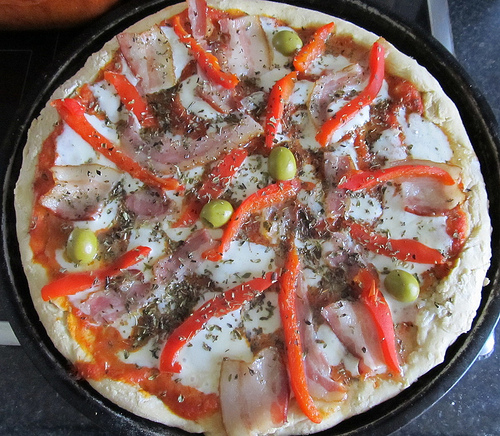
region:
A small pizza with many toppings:
[8, 3, 494, 433]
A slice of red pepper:
[277, 246, 321, 423]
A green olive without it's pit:
[198, 200, 234, 228]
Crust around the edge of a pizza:
[38, 304, 184, 425]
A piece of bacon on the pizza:
[39, 160, 125, 220]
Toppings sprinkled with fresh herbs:
[53, 85, 235, 229]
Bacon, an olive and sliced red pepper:
[339, 217, 449, 382]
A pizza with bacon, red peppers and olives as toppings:
[4, 3, 490, 433]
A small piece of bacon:
[113, 27, 180, 96]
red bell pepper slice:
[278, 245, 332, 427]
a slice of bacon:
[212, 336, 305, 434]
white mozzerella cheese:
[51, 104, 132, 179]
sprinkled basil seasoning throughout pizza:
[110, 60, 407, 335]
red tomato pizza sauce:
[21, 221, 61, 267]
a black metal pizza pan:
[5, 0, 495, 431]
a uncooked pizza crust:
[5, 10, 495, 435]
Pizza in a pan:
[40, 46, 412, 418]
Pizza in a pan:
[30, 20, 412, 408]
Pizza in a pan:
[13, 182, 434, 425]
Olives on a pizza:
[66, 228, 118, 265]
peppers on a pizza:
[156, 280, 288, 363]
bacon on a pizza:
[203, 320, 305, 433]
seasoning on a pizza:
[63, 120, 357, 351]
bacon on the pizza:
[121, 28, 183, 93]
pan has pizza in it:
[3, 1, 499, 434]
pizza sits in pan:
[14, 0, 493, 434]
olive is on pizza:
[267, 146, 297, 182]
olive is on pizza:
[199, 199, 234, 228]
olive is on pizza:
[382, 268, 424, 303]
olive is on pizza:
[64, 224, 97, 269]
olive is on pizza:
[271, 29, 301, 57]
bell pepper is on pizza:
[349, 266, 404, 379]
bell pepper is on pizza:
[336, 161, 463, 198]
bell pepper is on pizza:
[36, 243, 154, 300]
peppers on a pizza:
[51, 97, 171, 214]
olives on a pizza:
[65, 224, 117, 286]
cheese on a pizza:
[185, 328, 233, 376]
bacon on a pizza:
[201, 360, 272, 427]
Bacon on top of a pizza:
[100, 28, 383, 273]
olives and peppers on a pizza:
[196, 148, 346, 283]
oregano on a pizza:
[136, 124, 376, 349]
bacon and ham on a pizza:
[98, 59, 266, 193]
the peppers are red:
[279, 248, 324, 434]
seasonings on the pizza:
[196, 167, 362, 299]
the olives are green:
[197, 192, 234, 230]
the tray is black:
[442, 323, 481, 385]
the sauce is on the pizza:
[29, 207, 77, 285]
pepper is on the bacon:
[275, 340, 347, 419]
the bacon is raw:
[222, 350, 287, 415]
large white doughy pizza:
[13, 1, 493, 433]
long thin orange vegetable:
[280, 247, 324, 422]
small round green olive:
[66, 225, 96, 267]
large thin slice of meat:
[218, 358, 284, 433]